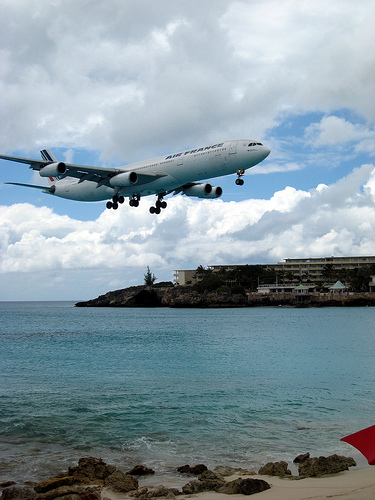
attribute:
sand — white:
[255, 436, 315, 490]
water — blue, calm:
[89, 291, 147, 386]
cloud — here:
[188, 20, 255, 96]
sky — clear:
[94, 64, 365, 295]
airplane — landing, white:
[27, 129, 236, 231]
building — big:
[200, 227, 324, 293]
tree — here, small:
[134, 262, 166, 299]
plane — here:
[6, 133, 305, 216]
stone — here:
[181, 461, 237, 487]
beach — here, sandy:
[19, 436, 370, 479]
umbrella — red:
[317, 418, 364, 461]